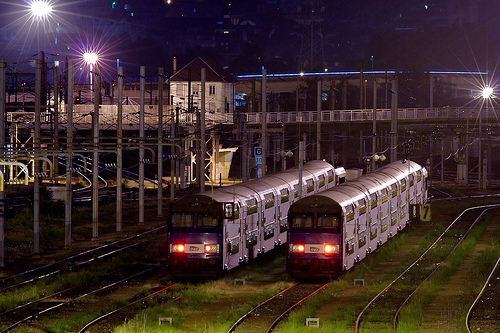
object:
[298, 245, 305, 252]
lights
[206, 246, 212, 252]
lights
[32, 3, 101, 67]
lights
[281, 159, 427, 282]
train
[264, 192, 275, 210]
window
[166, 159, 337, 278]
train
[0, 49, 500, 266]
fence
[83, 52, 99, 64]
light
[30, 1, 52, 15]
light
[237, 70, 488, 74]
lights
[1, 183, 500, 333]
train tracks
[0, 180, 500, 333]
ground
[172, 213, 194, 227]
front windows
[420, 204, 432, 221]
sign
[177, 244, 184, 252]
lights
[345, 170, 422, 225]
many windows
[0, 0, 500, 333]
picture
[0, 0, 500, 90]
sky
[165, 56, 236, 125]
building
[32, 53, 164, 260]
poles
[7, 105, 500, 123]
walkway